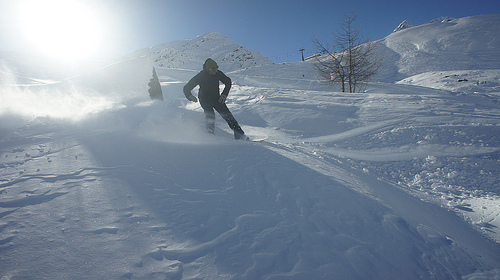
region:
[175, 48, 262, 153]
skier in the snow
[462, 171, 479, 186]
patch of white snow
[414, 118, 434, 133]
patch of white snow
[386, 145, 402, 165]
patch of white snow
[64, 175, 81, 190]
patch of white snow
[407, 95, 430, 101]
patch of white snow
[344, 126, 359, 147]
patch of white snow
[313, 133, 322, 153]
patch of white snow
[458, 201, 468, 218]
patch of white snow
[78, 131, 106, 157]
patch of white snow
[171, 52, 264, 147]
Person snowboarding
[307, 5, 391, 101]
Bare trees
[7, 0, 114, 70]
Very bright sun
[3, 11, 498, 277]
Snow covered mountains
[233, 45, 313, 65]
Ski Lift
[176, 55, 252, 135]
Black Snowsuit worn by snowboarder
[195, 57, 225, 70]
Hat worn by snowboarder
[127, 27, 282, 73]
Mountain behind snowboarder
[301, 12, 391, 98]
Two trees growing together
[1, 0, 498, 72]
Clear blue, cloudless sky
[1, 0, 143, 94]
A very bright sun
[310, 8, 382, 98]
Bare trees in the snow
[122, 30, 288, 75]
A mountain in the background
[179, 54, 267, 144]
A person in the snow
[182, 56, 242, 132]
A person wearing a black suit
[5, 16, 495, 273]
Snow on the ground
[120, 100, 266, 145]
Snow flying into the air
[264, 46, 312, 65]
A chair lift in the background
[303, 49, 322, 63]
A red building in the background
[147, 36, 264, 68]
Rocks under the snow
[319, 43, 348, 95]
tree in the snow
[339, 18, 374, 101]
tree in the snow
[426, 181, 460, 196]
patch of white snow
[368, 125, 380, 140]
patch of white snow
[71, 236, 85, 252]
patch of white snow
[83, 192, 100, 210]
patch of white snow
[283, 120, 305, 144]
patch of white snow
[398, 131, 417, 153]
patch of white snow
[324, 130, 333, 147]
patch of white snow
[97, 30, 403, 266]
a person skiing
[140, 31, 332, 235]
a person skiing during the day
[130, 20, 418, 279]
a person skiing in snow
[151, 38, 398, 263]
a person leaning on skies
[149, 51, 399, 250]
a skiier in the snow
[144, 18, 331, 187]
a skier during the day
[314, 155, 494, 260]
snow covered ground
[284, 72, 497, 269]
white snow covered ground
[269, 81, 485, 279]
ground covered in snow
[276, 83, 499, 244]
snow covered white ground